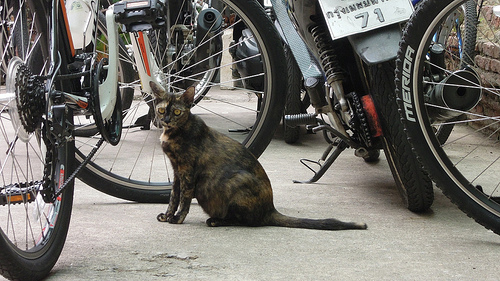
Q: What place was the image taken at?
A: It was taken at the sidewalk.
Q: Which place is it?
A: It is a sidewalk.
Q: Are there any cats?
A: Yes, there is a cat.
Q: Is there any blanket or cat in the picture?
A: Yes, there is a cat.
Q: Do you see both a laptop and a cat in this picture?
A: No, there is a cat but no laptops.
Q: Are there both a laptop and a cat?
A: No, there is a cat but no laptops.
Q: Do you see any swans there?
A: No, there are no swans.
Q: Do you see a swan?
A: No, there are no swans.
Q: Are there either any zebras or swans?
A: No, there are no swans or zebras.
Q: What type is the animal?
A: The animal is a cat.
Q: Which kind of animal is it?
A: The animal is a cat.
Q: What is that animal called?
A: This is a cat.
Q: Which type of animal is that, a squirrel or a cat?
A: This is a cat.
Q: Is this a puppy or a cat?
A: This is a cat.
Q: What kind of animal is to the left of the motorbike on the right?
A: The animal is a cat.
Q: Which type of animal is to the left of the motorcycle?
A: The animal is a cat.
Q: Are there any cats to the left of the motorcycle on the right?
A: Yes, there is a cat to the left of the motorcycle.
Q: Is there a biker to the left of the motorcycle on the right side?
A: No, there is a cat to the left of the motorbike.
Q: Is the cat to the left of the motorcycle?
A: Yes, the cat is to the left of the motorcycle.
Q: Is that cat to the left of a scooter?
A: No, the cat is to the left of the motorcycle.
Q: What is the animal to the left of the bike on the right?
A: The animal is a cat.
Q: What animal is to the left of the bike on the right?
A: The animal is a cat.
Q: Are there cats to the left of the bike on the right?
A: Yes, there is a cat to the left of the bike.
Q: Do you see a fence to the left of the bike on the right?
A: No, there is a cat to the left of the bike.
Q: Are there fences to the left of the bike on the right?
A: No, there is a cat to the left of the bike.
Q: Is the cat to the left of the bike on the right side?
A: Yes, the cat is to the left of the bike.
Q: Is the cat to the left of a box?
A: No, the cat is to the left of the bike.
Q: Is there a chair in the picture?
A: No, there are no chairs.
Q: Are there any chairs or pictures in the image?
A: No, there are no chairs or pictures.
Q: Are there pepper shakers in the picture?
A: No, there are no pepper shakers.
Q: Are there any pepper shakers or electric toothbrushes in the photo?
A: No, there are no pepper shakers or electric toothbrushes.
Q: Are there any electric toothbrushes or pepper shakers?
A: No, there are no pepper shakers or electric toothbrushes.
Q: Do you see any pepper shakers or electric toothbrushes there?
A: No, there are no pepper shakers or electric toothbrushes.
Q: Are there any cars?
A: No, there are no cars.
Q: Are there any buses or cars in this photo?
A: No, there are no cars or buses.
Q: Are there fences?
A: No, there are no fences.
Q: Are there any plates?
A: Yes, there is a plate.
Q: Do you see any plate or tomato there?
A: Yes, there is a plate.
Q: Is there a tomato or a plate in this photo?
A: Yes, there is a plate.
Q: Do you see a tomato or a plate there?
A: Yes, there is a plate.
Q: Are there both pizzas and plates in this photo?
A: No, there is a plate but no pizzas.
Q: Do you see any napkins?
A: No, there are no napkins.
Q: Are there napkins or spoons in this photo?
A: No, there are no napkins or spoons.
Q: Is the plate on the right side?
A: Yes, the plate is on the right of the image.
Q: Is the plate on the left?
A: No, the plate is on the right of the image.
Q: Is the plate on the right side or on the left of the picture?
A: The plate is on the right of the image.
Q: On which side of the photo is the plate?
A: The plate is on the right of the image.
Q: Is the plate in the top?
A: Yes, the plate is in the top of the image.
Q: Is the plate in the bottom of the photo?
A: No, the plate is in the top of the image.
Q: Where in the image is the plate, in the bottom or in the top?
A: The plate is in the top of the image.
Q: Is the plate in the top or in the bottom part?
A: The plate is in the top of the image.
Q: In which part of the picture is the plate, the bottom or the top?
A: The plate is in the top of the image.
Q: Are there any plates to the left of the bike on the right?
A: Yes, there is a plate to the left of the bike.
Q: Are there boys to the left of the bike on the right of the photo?
A: No, there is a plate to the left of the bike.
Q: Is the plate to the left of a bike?
A: Yes, the plate is to the left of a bike.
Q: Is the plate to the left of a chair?
A: No, the plate is to the left of a bike.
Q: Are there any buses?
A: No, there are no buses.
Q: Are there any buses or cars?
A: No, there are no buses or cars.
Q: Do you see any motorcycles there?
A: Yes, there is a motorcycle.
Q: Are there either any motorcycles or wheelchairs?
A: Yes, there is a motorcycle.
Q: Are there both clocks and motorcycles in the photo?
A: No, there is a motorcycle but no clocks.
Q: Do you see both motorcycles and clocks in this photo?
A: No, there is a motorcycle but no clocks.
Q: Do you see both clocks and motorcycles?
A: No, there is a motorcycle but no clocks.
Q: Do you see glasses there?
A: No, there are no glasses.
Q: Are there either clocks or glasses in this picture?
A: No, there are no glasses or clocks.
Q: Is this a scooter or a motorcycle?
A: This is a motorcycle.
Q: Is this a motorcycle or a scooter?
A: This is a motorcycle.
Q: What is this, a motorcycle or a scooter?
A: This is a motorcycle.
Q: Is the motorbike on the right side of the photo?
A: Yes, the motorbike is on the right of the image.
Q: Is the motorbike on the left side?
A: No, the motorbike is on the right of the image.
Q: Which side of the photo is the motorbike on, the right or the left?
A: The motorbike is on the right of the image.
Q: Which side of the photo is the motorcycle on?
A: The motorcycle is on the right of the image.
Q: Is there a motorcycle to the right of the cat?
A: Yes, there is a motorcycle to the right of the cat.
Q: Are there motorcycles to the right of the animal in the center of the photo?
A: Yes, there is a motorcycle to the right of the cat.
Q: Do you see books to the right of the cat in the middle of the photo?
A: No, there is a motorcycle to the right of the cat.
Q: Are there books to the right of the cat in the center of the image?
A: No, there is a motorcycle to the right of the cat.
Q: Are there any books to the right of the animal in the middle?
A: No, there is a motorcycle to the right of the cat.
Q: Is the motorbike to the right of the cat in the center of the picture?
A: Yes, the motorbike is to the right of the cat.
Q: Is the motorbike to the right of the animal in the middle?
A: Yes, the motorbike is to the right of the cat.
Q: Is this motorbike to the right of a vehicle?
A: No, the motorbike is to the right of the cat.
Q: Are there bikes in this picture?
A: Yes, there is a bike.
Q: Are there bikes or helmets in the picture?
A: Yes, there is a bike.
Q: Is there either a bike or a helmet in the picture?
A: Yes, there is a bike.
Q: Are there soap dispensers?
A: No, there are no soap dispensers.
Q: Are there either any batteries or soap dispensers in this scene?
A: No, there are no soap dispensers or batteries.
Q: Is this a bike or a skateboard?
A: This is a bike.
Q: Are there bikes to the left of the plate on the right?
A: Yes, there is a bike to the left of the plate.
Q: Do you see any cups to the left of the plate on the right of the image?
A: No, there is a bike to the left of the plate.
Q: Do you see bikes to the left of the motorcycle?
A: Yes, there is a bike to the left of the motorcycle.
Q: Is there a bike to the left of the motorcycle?
A: Yes, there is a bike to the left of the motorcycle.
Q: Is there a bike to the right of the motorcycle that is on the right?
A: No, the bike is to the left of the motorbike.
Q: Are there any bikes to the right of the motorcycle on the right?
A: No, the bike is to the left of the motorbike.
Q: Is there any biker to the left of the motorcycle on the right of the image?
A: No, there is a bike to the left of the motorcycle.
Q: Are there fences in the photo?
A: No, there are no fences.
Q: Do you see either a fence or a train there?
A: No, there are no fences or trains.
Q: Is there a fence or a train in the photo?
A: No, there are no fences or trains.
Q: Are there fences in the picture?
A: No, there are no fences.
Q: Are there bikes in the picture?
A: Yes, there is a bike.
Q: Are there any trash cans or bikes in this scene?
A: Yes, there is a bike.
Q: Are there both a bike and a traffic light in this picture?
A: No, there is a bike but no traffic lights.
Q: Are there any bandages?
A: No, there are no bandages.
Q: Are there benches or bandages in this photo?
A: No, there are no bandages or benches.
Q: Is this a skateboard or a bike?
A: This is a bike.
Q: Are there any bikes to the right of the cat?
A: Yes, there is a bike to the right of the cat.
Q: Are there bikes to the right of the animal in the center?
A: Yes, there is a bike to the right of the cat.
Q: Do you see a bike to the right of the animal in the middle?
A: Yes, there is a bike to the right of the cat.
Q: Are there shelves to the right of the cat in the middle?
A: No, there is a bike to the right of the cat.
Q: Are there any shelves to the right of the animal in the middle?
A: No, there is a bike to the right of the cat.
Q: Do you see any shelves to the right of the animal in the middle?
A: No, there is a bike to the right of the cat.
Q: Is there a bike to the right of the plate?
A: Yes, there is a bike to the right of the plate.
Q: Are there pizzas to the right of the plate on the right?
A: No, there is a bike to the right of the plate.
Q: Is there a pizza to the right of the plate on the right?
A: No, there is a bike to the right of the plate.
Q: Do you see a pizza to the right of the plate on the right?
A: No, there is a bike to the right of the plate.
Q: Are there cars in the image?
A: No, there are no cars.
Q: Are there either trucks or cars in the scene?
A: No, there are no cars or trucks.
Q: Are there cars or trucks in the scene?
A: No, there are no cars or trucks.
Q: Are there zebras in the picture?
A: No, there are no zebras.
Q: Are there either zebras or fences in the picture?
A: No, there are no zebras or fences.